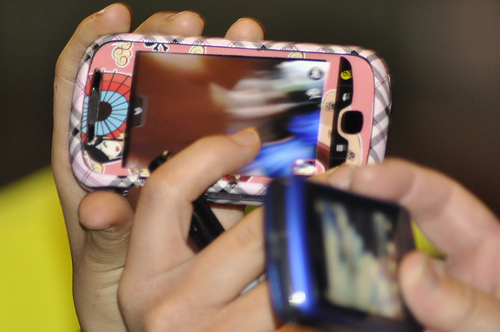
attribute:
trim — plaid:
[74, 29, 395, 198]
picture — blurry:
[119, 50, 336, 189]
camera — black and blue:
[264, 175, 425, 329]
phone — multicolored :
[78, 30, 435, 225]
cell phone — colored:
[65, 20, 392, 209]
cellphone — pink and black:
[68, 27, 393, 196]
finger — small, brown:
[396, 248, 496, 329]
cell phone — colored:
[66, 30, 393, 197]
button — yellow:
[339, 71, 354, 82]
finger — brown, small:
[153, 142, 215, 210]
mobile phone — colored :
[85, 28, 392, 195]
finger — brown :
[352, 157, 498, 287]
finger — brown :
[127, 115, 264, 273]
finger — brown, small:
[128, 144, 201, 214]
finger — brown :
[222, 9, 262, 49]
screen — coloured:
[122, 48, 330, 183]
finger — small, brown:
[69, 188, 134, 240]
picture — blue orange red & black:
[73, 60, 367, 206]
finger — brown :
[101, 117, 238, 247]